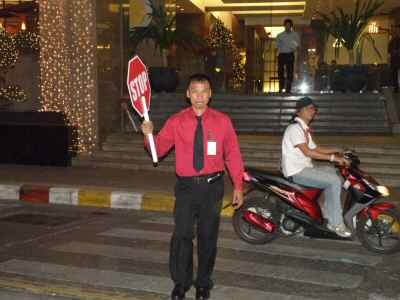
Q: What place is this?
A: It is a road.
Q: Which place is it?
A: It is a road.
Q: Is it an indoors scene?
A: Yes, it is indoors.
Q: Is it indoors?
A: Yes, it is indoors.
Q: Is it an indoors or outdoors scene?
A: It is indoors.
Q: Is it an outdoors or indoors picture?
A: It is indoors.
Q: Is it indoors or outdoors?
A: It is indoors.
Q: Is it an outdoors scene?
A: No, it is indoors.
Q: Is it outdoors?
A: No, it is indoors.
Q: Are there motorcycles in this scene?
A: Yes, there is a motorcycle.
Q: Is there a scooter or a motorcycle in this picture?
A: Yes, there is a motorcycle.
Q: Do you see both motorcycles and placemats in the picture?
A: No, there is a motorcycle but no placemats.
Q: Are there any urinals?
A: No, there are no urinals.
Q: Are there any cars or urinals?
A: No, there are no urinals or cars.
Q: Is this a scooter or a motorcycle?
A: This is a motorcycle.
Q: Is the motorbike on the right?
A: Yes, the motorbike is on the right of the image.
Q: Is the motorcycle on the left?
A: No, the motorcycle is on the right of the image.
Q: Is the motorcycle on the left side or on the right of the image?
A: The motorcycle is on the right of the image.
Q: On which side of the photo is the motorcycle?
A: The motorcycle is on the right of the image.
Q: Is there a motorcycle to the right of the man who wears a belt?
A: Yes, there is a motorcycle to the right of the man.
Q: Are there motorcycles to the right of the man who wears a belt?
A: Yes, there is a motorcycle to the right of the man.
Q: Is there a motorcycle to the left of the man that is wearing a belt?
A: No, the motorcycle is to the right of the man.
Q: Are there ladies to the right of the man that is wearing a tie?
A: No, there is a motorcycle to the right of the man.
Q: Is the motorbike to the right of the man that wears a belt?
A: Yes, the motorbike is to the right of the man.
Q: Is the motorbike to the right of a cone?
A: No, the motorbike is to the right of the man.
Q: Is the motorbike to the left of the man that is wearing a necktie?
A: No, the motorbike is to the right of the man.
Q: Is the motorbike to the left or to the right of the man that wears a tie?
A: The motorbike is to the right of the man.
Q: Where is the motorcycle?
A: The motorcycle is on the road.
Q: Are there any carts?
A: No, there are no carts.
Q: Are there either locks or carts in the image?
A: No, there are no carts or locks.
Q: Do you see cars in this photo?
A: No, there are no cars.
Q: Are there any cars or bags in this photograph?
A: No, there are no cars or bags.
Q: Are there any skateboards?
A: No, there are no skateboards.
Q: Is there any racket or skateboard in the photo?
A: No, there are no skateboards or rackets.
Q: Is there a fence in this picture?
A: No, there are no fences.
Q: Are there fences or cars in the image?
A: No, there are no fences or cars.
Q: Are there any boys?
A: No, there are no boys.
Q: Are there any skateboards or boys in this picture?
A: No, there are no boys or skateboards.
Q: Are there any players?
A: No, there are no players.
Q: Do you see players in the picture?
A: No, there are no players.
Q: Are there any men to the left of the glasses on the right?
A: Yes, there is a man to the left of the glasses.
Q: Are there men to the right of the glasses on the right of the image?
A: No, the man is to the left of the glasses.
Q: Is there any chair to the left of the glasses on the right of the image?
A: No, there is a man to the left of the glasses.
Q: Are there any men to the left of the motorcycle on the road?
A: Yes, there is a man to the left of the motorbike.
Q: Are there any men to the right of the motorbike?
A: No, the man is to the left of the motorbike.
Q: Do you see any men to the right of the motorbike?
A: No, the man is to the left of the motorbike.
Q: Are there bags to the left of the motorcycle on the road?
A: No, there is a man to the left of the motorbike.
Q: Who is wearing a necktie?
A: The man is wearing a necktie.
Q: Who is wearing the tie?
A: The man is wearing a necktie.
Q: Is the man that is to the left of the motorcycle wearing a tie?
A: Yes, the man is wearing a tie.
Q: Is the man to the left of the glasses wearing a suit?
A: No, the man is wearing a tie.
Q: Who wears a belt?
A: The man wears a belt.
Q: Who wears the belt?
A: The man wears a belt.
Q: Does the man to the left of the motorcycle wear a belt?
A: Yes, the man wears a belt.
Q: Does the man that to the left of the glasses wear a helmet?
A: No, the man wears a belt.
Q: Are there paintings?
A: No, there are no paintings.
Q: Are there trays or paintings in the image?
A: No, there are no paintings or trays.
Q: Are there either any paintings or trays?
A: No, there are no paintings or trays.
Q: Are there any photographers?
A: No, there are no photographers.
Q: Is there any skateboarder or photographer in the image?
A: No, there are no photographers or skateboarders.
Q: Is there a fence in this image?
A: No, there are no fences.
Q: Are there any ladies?
A: No, there are no ladies.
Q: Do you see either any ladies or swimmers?
A: No, there are no ladies or swimmers.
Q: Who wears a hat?
A: The man wears a hat.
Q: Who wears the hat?
A: The man wears a hat.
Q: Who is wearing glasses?
A: The man is wearing glasses.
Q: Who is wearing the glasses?
A: The man is wearing glasses.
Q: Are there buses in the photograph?
A: No, there are no buses.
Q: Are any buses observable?
A: No, there are no buses.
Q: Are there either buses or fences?
A: No, there are no buses or fences.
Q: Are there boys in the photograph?
A: No, there are no boys.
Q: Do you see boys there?
A: No, there are no boys.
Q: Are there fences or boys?
A: No, there are no boys or fences.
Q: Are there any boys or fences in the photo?
A: No, there are no boys or fences.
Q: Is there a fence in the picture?
A: No, there are no fences.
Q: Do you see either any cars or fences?
A: No, there are no fences or cars.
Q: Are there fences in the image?
A: No, there are no fences.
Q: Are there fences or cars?
A: No, there are no fences or cars.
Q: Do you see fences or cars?
A: No, there are no fences or cars.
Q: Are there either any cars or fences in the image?
A: No, there are no fences or cars.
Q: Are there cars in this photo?
A: No, there are no cars.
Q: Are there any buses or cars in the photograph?
A: No, there are no cars or buses.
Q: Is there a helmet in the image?
A: No, there are no helmets.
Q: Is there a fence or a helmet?
A: No, there are no helmets or fences.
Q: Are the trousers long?
A: Yes, the trousers are long.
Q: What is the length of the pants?
A: The pants are long.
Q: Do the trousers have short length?
A: No, the trousers are long.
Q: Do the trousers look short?
A: No, the trousers are long.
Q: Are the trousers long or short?
A: The trousers are long.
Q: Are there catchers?
A: No, there are no catchers.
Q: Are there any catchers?
A: No, there are no catchers.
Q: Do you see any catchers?
A: No, there are no catchers.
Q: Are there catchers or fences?
A: No, there are no catchers or fences.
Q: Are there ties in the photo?
A: Yes, there is a tie.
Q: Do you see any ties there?
A: Yes, there is a tie.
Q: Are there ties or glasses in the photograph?
A: Yes, there is a tie.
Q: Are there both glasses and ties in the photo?
A: Yes, there are both a tie and glasses.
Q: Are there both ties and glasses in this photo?
A: Yes, there are both a tie and glasses.